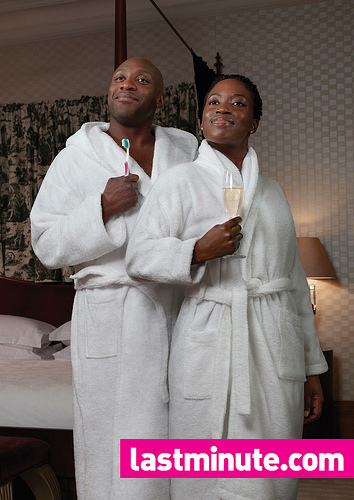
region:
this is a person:
[157, 66, 351, 497]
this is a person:
[28, 54, 199, 497]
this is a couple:
[25, 27, 314, 495]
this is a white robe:
[163, 150, 283, 342]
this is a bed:
[4, 320, 64, 446]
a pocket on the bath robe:
[75, 292, 126, 355]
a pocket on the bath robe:
[172, 325, 224, 404]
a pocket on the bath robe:
[276, 302, 320, 396]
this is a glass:
[210, 153, 255, 267]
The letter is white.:
[123, 440, 142, 472]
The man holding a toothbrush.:
[25, 40, 197, 276]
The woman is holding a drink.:
[119, 70, 315, 304]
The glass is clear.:
[209, 163, 262, 270]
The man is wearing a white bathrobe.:
[24, 49, 205, 497]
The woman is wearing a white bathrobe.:
[116, 66, 329, 497]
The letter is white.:
[139, 449, 157, 474]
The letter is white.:
[157, 451, 173, 473]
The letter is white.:
[172, 447, 184, 474]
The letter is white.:
[183, 448, 211, 473]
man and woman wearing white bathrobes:
[29, 58, 329, 432]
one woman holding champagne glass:
[185, 71, 266, 263]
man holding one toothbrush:
[70, 46, 159, 210]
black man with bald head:
[105, 53, 166, 124]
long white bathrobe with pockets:
[136, 148, 328, 434]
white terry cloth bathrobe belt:
[183, 279, 296, 419]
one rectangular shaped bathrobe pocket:
[79, 290, 124, 359]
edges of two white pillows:
[5, 315, 70, 352]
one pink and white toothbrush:
[120, 136, 132, 175]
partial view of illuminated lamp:
[296, 231, 339, 322]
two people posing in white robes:
[28, 54, 331, 495]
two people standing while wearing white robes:
[27, 52, 330, 498]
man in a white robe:
[27, 54, 203, 498]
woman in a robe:
[121, 70, 323, 496]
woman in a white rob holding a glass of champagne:
[121, 69, 328, 494]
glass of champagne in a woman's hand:
[215, 162, 242, 257]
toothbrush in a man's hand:
[109, 134, 135, 176]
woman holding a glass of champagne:
[123, 72, 330, 498]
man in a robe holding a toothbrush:
[26, 56, 198, 497]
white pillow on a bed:
[0, 312, 57, 354]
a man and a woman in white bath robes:
[30, 44, 332, 370]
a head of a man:
[100, 55, 169, 121]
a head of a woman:
[194, 73, 265, 152]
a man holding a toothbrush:
[28, 52, 182, 237]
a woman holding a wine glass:
[187, 68, 299, 271]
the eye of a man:
[110, 71, 126, 83]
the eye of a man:
[135, 74, 151, 86]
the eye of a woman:
[205, 96, 222, 108]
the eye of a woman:
[230, 98, 249, 109]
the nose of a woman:
[213, 103, 234, 116]